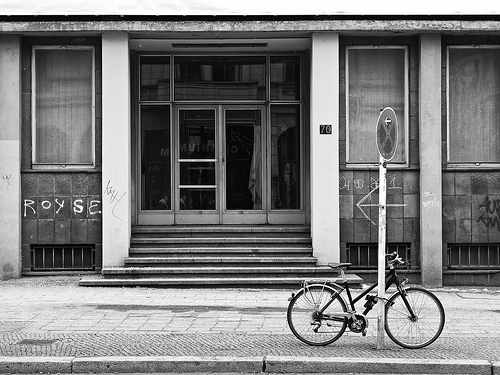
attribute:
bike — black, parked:
[286, 249, 447, 352]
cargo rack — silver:
[297, 273, 342, 288]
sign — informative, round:
[373, 106, 399, 169]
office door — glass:
[219, 105, 268, 227]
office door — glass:
[174, 102, 223, 230]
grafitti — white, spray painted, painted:
[23, 196, 105, 222]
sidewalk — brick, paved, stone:
[3, 284, 499, 367]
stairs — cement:
[78, 224, 363, 287]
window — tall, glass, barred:
[28, 44, 97, 173]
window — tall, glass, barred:
[343, 44, 410, 169]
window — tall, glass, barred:
[443, 42, 499, 173]